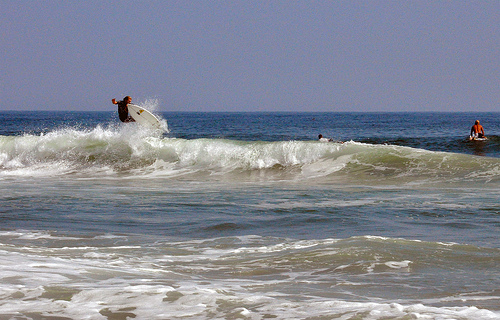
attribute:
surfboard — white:
[125, 102, 161, 129]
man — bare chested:
[468, 118, 488, 141]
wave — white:
[12, 134, 393, 179]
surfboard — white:
[125, 99, 167, 134]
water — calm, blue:
[0, 108, 497, 318]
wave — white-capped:
[22, 126, 331, 266]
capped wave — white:
[17, 133, 309, 167]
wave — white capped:
[332, 228, 439, 248]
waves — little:
[356, 133, 497, 190]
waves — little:
[3, 209, 495, 318]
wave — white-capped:
[0, 125, 493, 177]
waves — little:
[233, 215, 399, 315]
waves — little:
[64, 145, 275, 248]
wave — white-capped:
[4, 127, 498, 189]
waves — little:
[51, 100, 371, 197]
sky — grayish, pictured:
[0, 2, 500, 114]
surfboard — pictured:
[128, 105, 168, 135]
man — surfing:
[101, 84, 143, 125]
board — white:
[125, 101, 170, 134]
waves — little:
[124, 146, 304, 276]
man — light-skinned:
[462, 117, 489, 147]